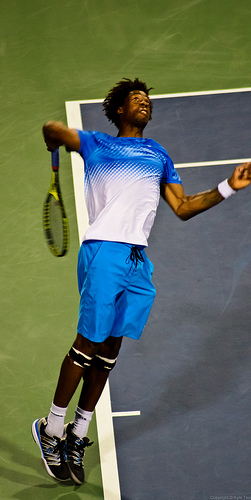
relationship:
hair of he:
[99, 77, 155, 125] [30, 75, 250, 486]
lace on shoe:
[76, 443, 85, 474] [59, 419, 95, 484]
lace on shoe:
[48, 440, 68, 470] [30, 415, 74, 482]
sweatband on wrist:
[213, 181, 234, 198] [223, 179, 235, 194]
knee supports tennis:
[64, 342, 91, 370] [36, 71, 250, 485]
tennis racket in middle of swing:
[47, 141, 71, 260] [27, 161, 91, 299]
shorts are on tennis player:
[67, 222, 158, 344] [31, 77, 224, 486]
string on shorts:
[126, 243, 145, 276] [75, 222, 156, 344]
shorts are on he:
[75, 222, 156, 344] [30, 75, 250, 486]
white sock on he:
[45, 398, 70, 439] [30, 75, 250, 486]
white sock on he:
[70, 402, 95, 440] [30, 75, 250, 486]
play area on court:
[64, 87, 248, 499] [51, 83, 246, 162]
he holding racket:
[43, 78, 243, 476] [41, 146, 71, 257]